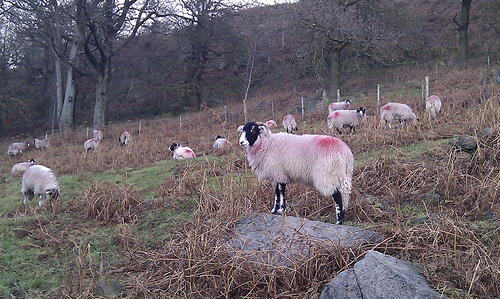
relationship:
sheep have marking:
[237, 121, 354, 224] [312, 134, 338, 153]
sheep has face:
[237, 121, 354, 224] [237, 122, 258, 147]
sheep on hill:
[237, 121, 354, 224] [2, 56, 499, 297]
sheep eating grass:
[237, 121, 354, 224] [120, 171, 161, 188]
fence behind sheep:
[0, 56, 496, 146] [237, 121, 354, 224]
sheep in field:
[237, 121, 354, 224] [3, 76, 499, 298]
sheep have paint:
[237, 121, 354, 224] [185, 149, 192, 155]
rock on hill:
[214, 212, 382, 279] [2, 56, 499, 297]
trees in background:
[1, 1, 499, 129] [1, 1, 499, 113]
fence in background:
[0, 56, 496, 146] [1, 1, 499, 113]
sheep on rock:
[237, 121, 354, 224] [214, 212, 382, 279]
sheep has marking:
[237, 121, 354, 224] [312, 134, 338, 153]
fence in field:
[0, 56, 496, 146] [3, 76, 499, 298]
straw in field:
[442, 160, 476, 200] [3, 76, 499, 298]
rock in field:
[214, 212, 382, 284] [3, 76, 499, 298]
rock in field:
[214, 212, 382, 279] [3, 76, 499, 298]